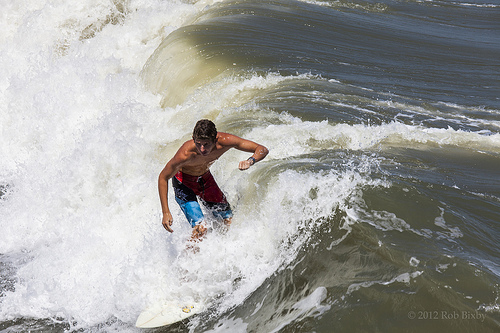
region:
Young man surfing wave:
[136, 119, 269, 329]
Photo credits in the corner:
[412, 310, 486, 320]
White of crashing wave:
[8, 12, 333, 331]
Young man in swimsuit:
[158, 118, 270, 233]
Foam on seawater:
[367, 204, 462, 286]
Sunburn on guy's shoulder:
[159, 122, 266, 238]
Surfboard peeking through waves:
[129, 291, 204, 326]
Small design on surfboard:
[180, 300, 195, 313]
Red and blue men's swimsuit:
[172, 173, 234, 226]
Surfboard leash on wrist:
[246, 152, 257, 164]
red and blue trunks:
[168, 174, 233, 225]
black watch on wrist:
[247, 155, 257, 165]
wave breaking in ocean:
[111, 3, 363, 332]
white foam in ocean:
[333, 117, 499, 157]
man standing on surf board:
[156, 120, 270, 242]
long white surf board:
[131, 285, 213, 332]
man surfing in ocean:
[138, 114, 268, 328]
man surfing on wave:
[134, 119, 269, 331]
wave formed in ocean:
[132, 2, 411, 331]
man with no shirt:
[157, 121, 270, 255]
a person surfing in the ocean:
[141, 112, 266, 239]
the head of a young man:
[178, 118, 222, 156]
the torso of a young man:
[175, 151, 215, 176]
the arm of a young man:
[218, 132, 262, 154]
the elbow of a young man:
[254, 136, 275, 158]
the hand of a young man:
[235, 149, 256, 171]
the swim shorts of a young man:
[172, 173, 243, 220]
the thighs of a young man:
[178, 193, 229, 221]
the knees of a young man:
[184, 213, 236, 231]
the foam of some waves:
[107, 235, 174, 302]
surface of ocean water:
[3, 5, 498, 327]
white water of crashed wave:
[0, 10, 174, 321]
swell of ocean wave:
[184, 6, 386, 308]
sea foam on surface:
[339, 206, 464, 300]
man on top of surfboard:
[133, 117, 268, 327]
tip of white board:
[135, 304, 190, 329]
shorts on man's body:
[174, 171, 231, 226]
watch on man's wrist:
[247, 154, 257, 166]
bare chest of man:
[182, 139, 232, 175]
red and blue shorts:
[172, 171, 231, 228]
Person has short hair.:
[191, 128, 215, 135]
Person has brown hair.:
[191, 115, 233, 140]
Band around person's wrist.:
[243, 155, 258, 164]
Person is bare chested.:
[181, 148, 233, 155]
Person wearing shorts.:
[171, 184, 233, 214]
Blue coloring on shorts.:
[181, 201, 213, 227]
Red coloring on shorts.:
[195, 178, 231, 195]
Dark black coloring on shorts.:
[173, 183, 198, 200]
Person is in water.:
[89, 110, 287, 283]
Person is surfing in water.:
[132, 124, 244, 316]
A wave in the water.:
[343, 120, 420, 159]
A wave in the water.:
[301, 174, 351, 213]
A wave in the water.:
[64, 26, 189, 256]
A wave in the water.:
[241, 197, 294, 270]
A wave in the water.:
[126, 18, 141, 50]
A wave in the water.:
[244, 78, 265, 103]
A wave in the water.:
[328, 252, 408, 294]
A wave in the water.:
[208, 287, 279, 331]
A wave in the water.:
[87, 48, 135, 160]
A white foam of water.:
[114, 201, 122, 210]